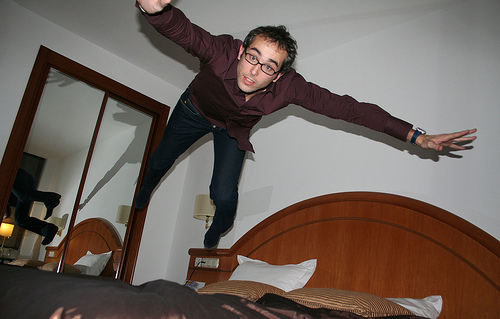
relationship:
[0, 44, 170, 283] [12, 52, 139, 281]
mirror on closet door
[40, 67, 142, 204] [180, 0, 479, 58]
shadow on ceiling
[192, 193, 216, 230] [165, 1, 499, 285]
lamp mounted wall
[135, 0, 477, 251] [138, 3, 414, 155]
man wearing shirt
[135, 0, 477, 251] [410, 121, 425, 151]
man wearing watch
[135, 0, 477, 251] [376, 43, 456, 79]
man in air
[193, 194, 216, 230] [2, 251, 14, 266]
lamp on table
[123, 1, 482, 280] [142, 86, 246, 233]
man wearing jeans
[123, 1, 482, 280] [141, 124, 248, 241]
man wearing jeans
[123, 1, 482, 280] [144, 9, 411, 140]
man wears shirt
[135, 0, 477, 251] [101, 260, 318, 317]
man jumps on bed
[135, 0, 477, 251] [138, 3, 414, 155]
man wears shirt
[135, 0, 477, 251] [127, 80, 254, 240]
man wears jeans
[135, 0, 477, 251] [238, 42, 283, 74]
man wears glasses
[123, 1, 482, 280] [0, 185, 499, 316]
man jumping on bed